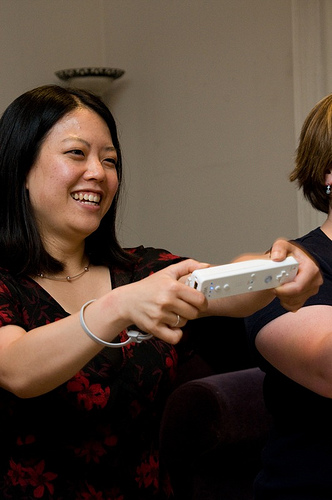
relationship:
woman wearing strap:
[1, 83, 325, 498] [78, 300, 160, 348]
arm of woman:
[2, 272, 132, 399] [1, 83, 325, 498]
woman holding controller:
[1, 83, 325, 498] [181, 254, 303, 298]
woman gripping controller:
[1, 83, 325, 498] [181, 254, 303, 298]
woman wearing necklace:
[1, 83, 325, 498] [31, 255, 93, 282]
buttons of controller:
[214, 283, 233, 295] [181, 254, 303, 298]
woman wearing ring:
[1, 83, 325, 498] [172, 313, 184, 327]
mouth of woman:
[70, 185, 105, 210] [1, 83, 325, 498]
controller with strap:
[181, 254, 303, 298] [78, 300, 160, 348]